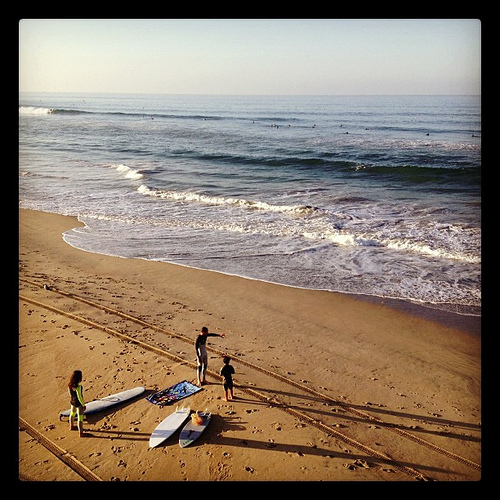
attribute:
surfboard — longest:
[53, 382, 149, 417]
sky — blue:
[19, 19, 479, 94]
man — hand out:
[192, 323, 224, 388]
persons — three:
[169, 316, 266, 401]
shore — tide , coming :
[19, 199, 499, 486]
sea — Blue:
[19, 92, 489, 300]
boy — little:
[219, 356, 234, 403]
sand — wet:
[243, 400, 320, 485]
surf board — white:
[150, 400, 185, 472]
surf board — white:
[174, 398, 217, 465]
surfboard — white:
[149, 405, 191, 445]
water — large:
[20, 92, 490, 262]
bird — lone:
[40, 281, 52, 291]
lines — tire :
[42, 276, 142, 351]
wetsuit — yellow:
[65, 382, 85, 419]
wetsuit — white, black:
[190, 332, 218, 379]